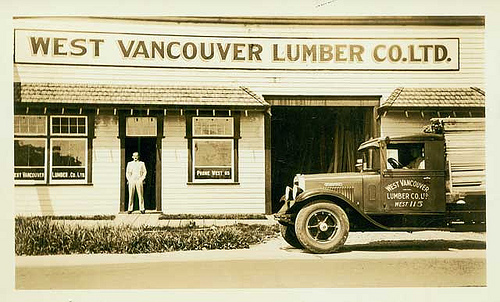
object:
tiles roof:
[381, 86, 485, 111]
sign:
[12, 29, 459, 71]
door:
[121, 135, 162, 214]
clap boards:
[160, 113, 187, 215]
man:
[125, 151, 147, 214]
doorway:
[119, 129, 164, 214]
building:
[11, 14, 485, 220]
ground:
[13, 202, 487, 287]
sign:
[193, 165, 235, 183]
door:
[381, 170, 436, 212]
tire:
[293, 199, 352, 254]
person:
[403, 144, 426, 171]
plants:
[16, 212, 278, 257]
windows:
[13, 115, 89, 185]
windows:
[188, 112, 242, 186]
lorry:
[273, 118, 486, 254]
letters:
[26, 37, 452, 65]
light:
[24, 104, 274, 117]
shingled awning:
[17, 81, 275, 120]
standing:
[125, 151, 150, 215]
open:
[119, 138, 157, 212]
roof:
[13, 78, 274, 120]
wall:
[7, 15, 486, 219]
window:
[387, 143, 424, 172]